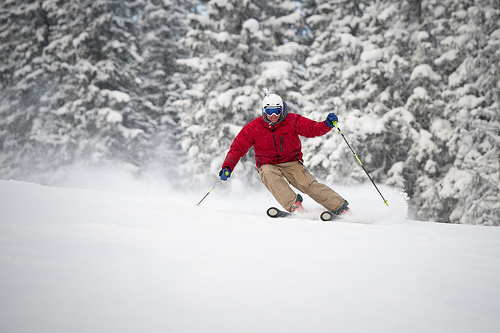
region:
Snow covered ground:
[22, 198, 159, 303]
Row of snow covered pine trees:
[44, 15, 471, 88]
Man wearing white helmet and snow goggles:
[251, 86, 291, 128]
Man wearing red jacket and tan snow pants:
[218, 120, 328, 206]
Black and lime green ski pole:
[331, 121, 377, 181]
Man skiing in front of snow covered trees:
[180, 67, 417, 248]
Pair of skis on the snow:
[260, 203, 389, 232]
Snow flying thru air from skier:
[348, 189, 412, 234]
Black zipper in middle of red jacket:
[269, 126, 284, 167]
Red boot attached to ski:
[287, 193, 307, 223]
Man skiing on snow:
[196, 94, 389, 224]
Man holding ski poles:
[198, 95, 386, 223]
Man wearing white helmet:
[262, 91, 287, 123]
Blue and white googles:
[263, 105, 280, 114]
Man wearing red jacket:
[224, 113, 331, 169]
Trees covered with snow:
[0, 34, 242, 145]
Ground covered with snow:
[9, 185, 291, 330]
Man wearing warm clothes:
[222, 95, 347, 222]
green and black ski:
[328, 122, 392, 203]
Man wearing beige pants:
[256, 152, 346, 212]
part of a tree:
[385, 49, 442, 116]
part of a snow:
[216, 262, 251, 300]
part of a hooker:
[363, 160, 380, 212]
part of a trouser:
[277, 177, 293, 188]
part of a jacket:
[261, 123, 293, 148]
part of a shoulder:
[245, 120, 258, 132]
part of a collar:
[266, 121, 281, 132]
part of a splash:
[386, 192, 459, 240]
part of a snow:
[180, 248, 243, 301]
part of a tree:
[438, 120, 480, 160]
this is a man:
[236, 95, 347, 217]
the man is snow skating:
[203, 90, 358, 215]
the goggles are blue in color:
[270, 108, 280, 113]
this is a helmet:
[265, 95, 280, 105]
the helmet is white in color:
[262, 95, 277, 100]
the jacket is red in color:
[281, 125, 296, 135]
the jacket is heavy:
[255, 127, 291, 152]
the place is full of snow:
[223, 249, 375, 311]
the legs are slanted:
[245, 168, 340, 206]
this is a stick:
[353, 143, 367, 172]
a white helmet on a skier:
[261, 93, 288, 119]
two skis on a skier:
[269, 190, 360, 227]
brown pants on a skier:
[256, 160, 354, 218]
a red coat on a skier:
[219, 112, 334, 165]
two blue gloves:
[217, 108, 346, 182]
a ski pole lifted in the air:
[322, 110, 410, 211]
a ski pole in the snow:
[187, 164, 232, 211]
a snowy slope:
[3, 165, 493, 326]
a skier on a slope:
[216, 87, 381, 222]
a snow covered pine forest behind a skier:
[5, 4, 496, 223]